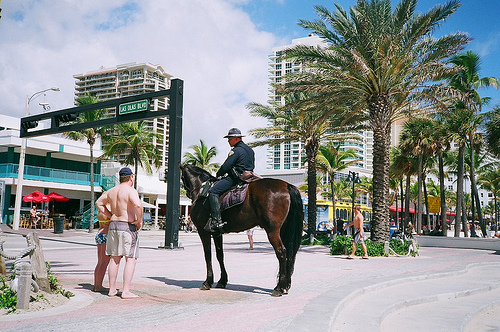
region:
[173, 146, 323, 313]
Brown horse on a sidewalk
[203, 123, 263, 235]
Police man on a horse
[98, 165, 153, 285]
Man without a shirt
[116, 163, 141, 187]
Hat on a man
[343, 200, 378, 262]
Man walking without a shirt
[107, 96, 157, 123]
Sign on a post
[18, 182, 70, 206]
Red umbrellas over a table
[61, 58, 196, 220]
Building by a road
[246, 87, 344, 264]
Palm tree by a road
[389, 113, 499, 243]
Group of palm trees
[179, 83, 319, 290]
a man sitting on a horse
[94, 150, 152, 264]
a man with no shirt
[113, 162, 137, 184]
a man wearing a blue hat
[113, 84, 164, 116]
green and white street sign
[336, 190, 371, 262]
a man walking on the sidewalk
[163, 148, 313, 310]
a dark brown horse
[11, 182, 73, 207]
two red umbrellas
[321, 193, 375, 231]
a yellow trolley car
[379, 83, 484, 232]
several tall palm trees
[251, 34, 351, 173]
a tall building with balconies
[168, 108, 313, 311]
officer sitting on horse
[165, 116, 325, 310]
officer sitting on horse in public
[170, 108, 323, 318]
officer sitting on horse during daytime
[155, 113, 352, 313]
officer sitting on horse in daylight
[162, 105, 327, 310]
officer on horse in public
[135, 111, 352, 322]
officer on horse in daytime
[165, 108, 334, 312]
officer on brown horse in public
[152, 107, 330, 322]
officer on healthy horse in public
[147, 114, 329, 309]
officer on nice brown horse in public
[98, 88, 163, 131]
green street sign in view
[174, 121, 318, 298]
a man on top of a horse.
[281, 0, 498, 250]
a palm tree near a man.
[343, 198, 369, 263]
a man walking past a palm tree.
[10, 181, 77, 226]
a sitting area near a building.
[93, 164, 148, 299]
a couple talking to a cop.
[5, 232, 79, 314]
cement pillars near a couple.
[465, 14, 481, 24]
a section of clear blue sky.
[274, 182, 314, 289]
a horse's long black tail.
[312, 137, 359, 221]
a palm tree near a tall building.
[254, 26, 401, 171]
a tall multi story building.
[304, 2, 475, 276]
a large palm tree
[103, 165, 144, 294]
a shirtless man on a walkway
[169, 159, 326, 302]
a beautiful brown horse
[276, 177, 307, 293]
a black tail on a horse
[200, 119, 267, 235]
a police officer on a horse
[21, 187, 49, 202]
a red umbrella in front of a building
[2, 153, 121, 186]
a blue railing on a balcony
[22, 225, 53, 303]
a bent over wooden post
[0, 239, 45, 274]
rope connected to wooden posts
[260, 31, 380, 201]
a tall concrete building